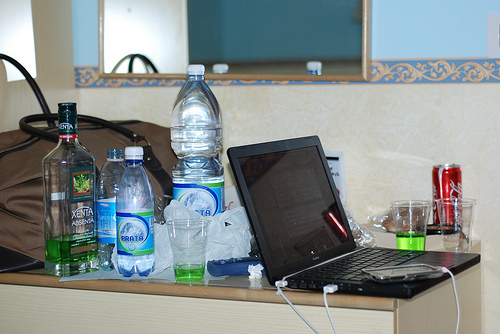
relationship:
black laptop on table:
[225, 133, 480, 301] [0, 222, 480, 332]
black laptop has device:
[225, 133, 480, 301] [358, 255, 448, 280]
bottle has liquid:
[44, 99, 100, 278] [45, 151, 99, 281]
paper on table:
[247, 259, 269, 290] [1, 266, 486, 329]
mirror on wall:
[105, 1, 366, 77] [69, 0, 499, 85]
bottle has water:
[167, 60, 227, 219] [168, 85, 218, 210]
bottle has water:
[112, 141, 157, 279] [168, 85, 218, 210]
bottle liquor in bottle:
[41, 230, 96, 276] [37, 94, 99, 281]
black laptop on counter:
[225, 133, 480, 301] [0, 253, 481, 330]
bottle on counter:
[44, 99, 100, 274] [0, 253, 481, 330]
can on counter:
[427, 163, 465, 226] [4, 224, 480, 321]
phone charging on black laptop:
[366, 255, 442, 282] [225, 133, 480, 301]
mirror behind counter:
[185, 1, 363, 63] [0, 253, 481, 330]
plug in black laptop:
[321, 283, 343, 331] [225, 133, 480, 301]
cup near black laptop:
[167, 211, 215, 287] [225, 133, 480, 301]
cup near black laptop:
[389, 193, 433, 250] [225, 133, 480, 301]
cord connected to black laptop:
[273, 278, 315, 332] [225, 133, 480, 301]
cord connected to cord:
[318, 281, 340, 332] [273, 278, 315, 332]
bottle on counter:
[167, 60, 227, 219] [0, 261, 481, 331]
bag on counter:
[2, 94, 192, 272] [0, 261, 481, 331]